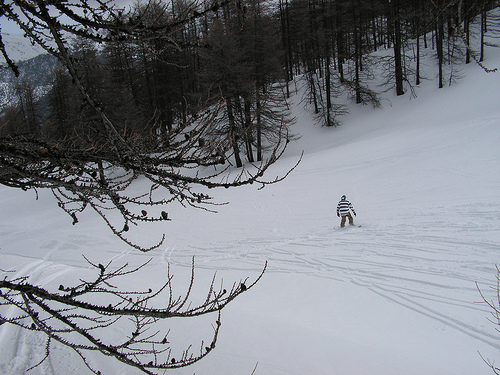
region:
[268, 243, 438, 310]
Ski tracks in the snow.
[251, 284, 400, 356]
The snow is white.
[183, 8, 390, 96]
Trees on the hill.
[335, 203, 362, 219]
The person jacket has stripes.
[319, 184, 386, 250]
The person is standingin the snow.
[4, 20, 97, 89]
Mountains covered with snow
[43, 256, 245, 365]
Branches on the tree.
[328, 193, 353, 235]
boy on bottom of hill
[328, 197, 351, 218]
black and white hoodie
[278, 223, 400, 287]
tracks in white snow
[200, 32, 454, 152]
bare trees on hill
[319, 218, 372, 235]
boy has grey pants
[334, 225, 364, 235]
boy is on snowboard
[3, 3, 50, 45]
grey sky in distance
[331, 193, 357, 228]
person standing in the snow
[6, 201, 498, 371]
lots of ski tracks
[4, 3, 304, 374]
tree branches in the foreground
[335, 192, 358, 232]
person wearing a striped coat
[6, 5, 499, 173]
pine trees in the background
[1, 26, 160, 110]
mountains in the background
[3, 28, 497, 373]
ground is covered with snow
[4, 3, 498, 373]
ski slope during the evening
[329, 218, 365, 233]
person's feet are hidden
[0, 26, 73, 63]
snow on top of the mountain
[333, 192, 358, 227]
a man is on the snow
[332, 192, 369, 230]
a man is skiing on the snow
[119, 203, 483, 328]
the snow is filled with tracks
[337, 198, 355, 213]
the man is wearing a striped sweater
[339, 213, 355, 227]
the man is wearing long pants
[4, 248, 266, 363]
a branch is in the front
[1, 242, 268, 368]
the branch is bare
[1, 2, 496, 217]
the trees are bare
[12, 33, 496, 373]
the snow is going downhill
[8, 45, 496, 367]
the snow is white in color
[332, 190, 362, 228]
man snowboarding down snowy hill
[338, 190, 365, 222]
person in stripped shirt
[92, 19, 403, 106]
trees with no leaves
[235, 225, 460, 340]
hill covered in snow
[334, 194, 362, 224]
person wearing a hat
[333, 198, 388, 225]
man on a snowboard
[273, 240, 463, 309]
trails in the snow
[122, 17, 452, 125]
many pine trees on a hill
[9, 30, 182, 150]
mountains covered in snow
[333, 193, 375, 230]
man in tan snow pants